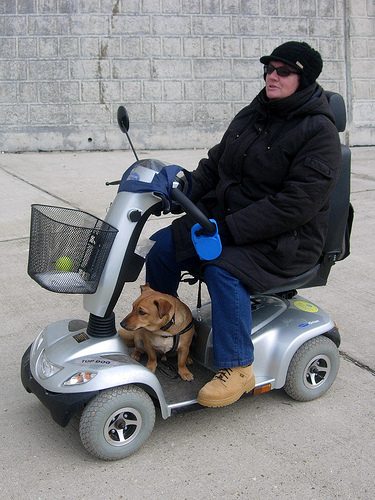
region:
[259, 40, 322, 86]
A black knitted hat on the head of a lady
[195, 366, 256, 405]
A brown colored boot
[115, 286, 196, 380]
A dog sitting on a scooter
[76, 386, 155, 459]
Front left tire on a scooter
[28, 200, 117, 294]
A basket on a scooter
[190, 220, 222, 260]
A retractable dog leash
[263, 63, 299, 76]
Sunglasses worn by a lady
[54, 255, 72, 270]
A tennis ball in a basket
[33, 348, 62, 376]
Front headlight of a scooter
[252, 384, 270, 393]
Reflector on the side of a scooter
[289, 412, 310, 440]
part of a floor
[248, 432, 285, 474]
part of a floor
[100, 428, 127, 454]
part of a wheel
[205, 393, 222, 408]
edge of a shoe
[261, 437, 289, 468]
part of a floor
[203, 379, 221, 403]
part of a short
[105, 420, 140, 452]
part of a wheel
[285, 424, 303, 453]
part of a floor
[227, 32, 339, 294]
this is a lady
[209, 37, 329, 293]
the lady is sitted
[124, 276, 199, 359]
this is a dog below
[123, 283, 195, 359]
the dog is brown in color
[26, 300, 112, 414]
this is a minicar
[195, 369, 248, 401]
the shoes are big in size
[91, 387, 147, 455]
this is the wheel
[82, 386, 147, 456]
the wheel is small in size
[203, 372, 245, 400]
the shoe is brown in color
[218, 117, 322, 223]
the jacket is warm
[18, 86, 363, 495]
A grey powerized scooter.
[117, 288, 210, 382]
A brown dog.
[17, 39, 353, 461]
A woman riding a motorized power scooter.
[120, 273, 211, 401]
A dog riding a scooter.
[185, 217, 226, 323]
A blue retractable leash.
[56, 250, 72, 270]
A green tennis ball.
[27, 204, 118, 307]
A black basket.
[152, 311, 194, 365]
A black dog harness.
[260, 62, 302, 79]
A pair of black sunglasses.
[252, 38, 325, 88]
A black knit hat.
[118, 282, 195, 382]
the dog sitting near the woman's feet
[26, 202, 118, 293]
the black basket on the scooter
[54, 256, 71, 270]
the ball in the black basket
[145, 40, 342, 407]
the woman sitting on the scooter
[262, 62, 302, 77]
the sunglasses on the woman's face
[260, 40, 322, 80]
the hat on the woman's head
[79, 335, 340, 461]
the wheels on the scooter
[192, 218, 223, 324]
the blue leash hanging from the handlebar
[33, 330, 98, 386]
the lights in front of the scooter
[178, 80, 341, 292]
the woman's large black jacket